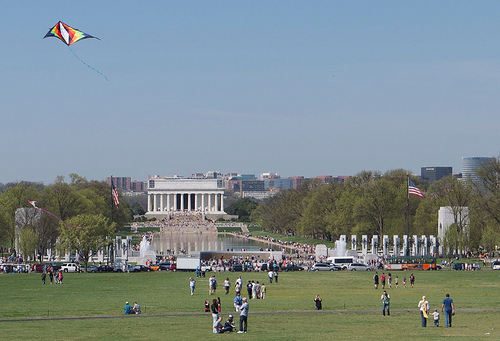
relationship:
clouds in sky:
[208, 25, 309, 108] [4, 4, 493, 194]